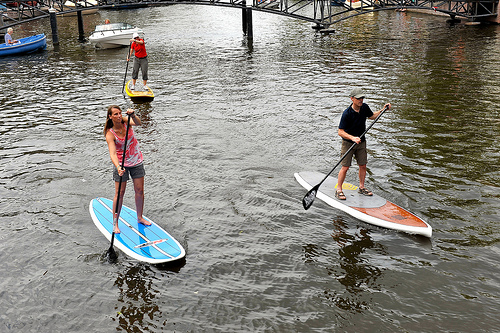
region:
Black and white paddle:
[298, 105, 388, 212]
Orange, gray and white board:
[291, 165, 426, 235]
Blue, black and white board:
[86, 195, 186, 265]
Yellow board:
[125, 80, 150, 96]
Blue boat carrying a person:
[0, 31, 45, 48]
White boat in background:
[88, 17, 138, 49]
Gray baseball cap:
[350, 86, 362, 96]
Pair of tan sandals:
[331, 186, 371, 196]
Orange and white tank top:
[106, 122, 141, 165]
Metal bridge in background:
[0, 0, 495, 45]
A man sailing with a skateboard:
[330, 79, 398, 195]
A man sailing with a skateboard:
[117, 32, 157, 99]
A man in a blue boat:
[3, 23, 47, 59]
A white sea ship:
[84, 24, 142, 41]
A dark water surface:
[193, 214, 333, 296]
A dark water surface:
[2, 230, 114, 327]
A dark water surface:
[187, 62, 292, 147]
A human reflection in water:
[305, 221, 380, 326]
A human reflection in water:
[110, 254, 147, 329]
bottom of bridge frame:
[0, 0, 497, 50]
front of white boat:
[87, 17, 142, 52]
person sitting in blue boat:
[0, 25, 47, 51]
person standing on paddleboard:
[121, 33, 153, 98]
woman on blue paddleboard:
[89, 105, 185, 264]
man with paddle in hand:
[301, 85, 391, 210]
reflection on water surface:
[1, 10, 493, 330]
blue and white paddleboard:
[88, 195, 183, 268]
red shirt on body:
[129, 36, 147, 56]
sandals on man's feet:
[336, 185, 373, 200]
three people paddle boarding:
[92, 28, 432, 261]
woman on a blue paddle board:
[87, 105, 184, 267]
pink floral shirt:
[110, 129, 140, 165]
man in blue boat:
[1, 28, 51, 50]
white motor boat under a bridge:
[90, 18, 133, 49]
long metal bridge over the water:
[3, 3, 498, 46]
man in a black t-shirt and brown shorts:
[298, 89, 433, 241]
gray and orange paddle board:
[297, 170, 431, 235]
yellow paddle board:
[126, 82, 153, 101]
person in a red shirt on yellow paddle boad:
[120, 35, 150, 89]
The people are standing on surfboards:
[15, 15, 497, 315]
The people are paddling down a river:
[1, 20, 486, 325]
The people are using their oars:
[1, 20, 496, 321]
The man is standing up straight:
[285, 60, 447, 280]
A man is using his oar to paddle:
[271, 55, 451, 291]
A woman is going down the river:
[81, 97, 198, 295]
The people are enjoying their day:
[6, 17, 492, 317]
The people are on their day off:
[13, 20, 456, 321]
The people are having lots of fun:
[10, 10, 481, 325]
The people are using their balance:
[10, 16, 481, 320]